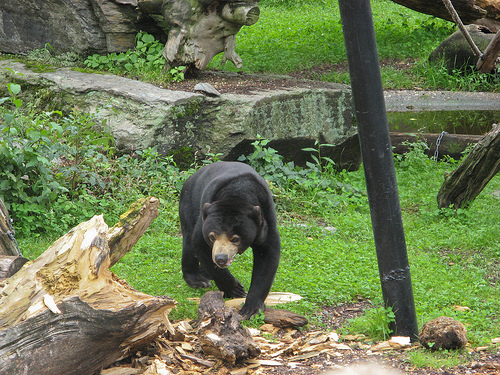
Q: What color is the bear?
A: Black.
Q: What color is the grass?
A: Green.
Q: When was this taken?
A: Daytime.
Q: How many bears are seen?
A: 1.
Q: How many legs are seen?
A: 3.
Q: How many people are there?
A: 0.